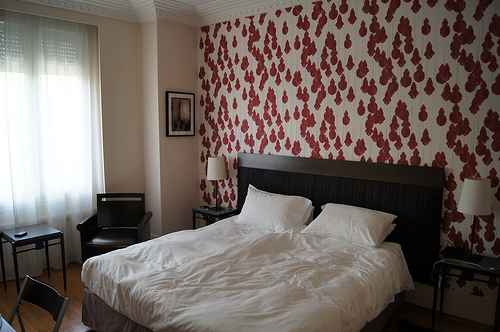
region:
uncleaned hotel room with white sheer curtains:
[2, 2, 498, 329]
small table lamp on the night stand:
[205, 154, 229, 210]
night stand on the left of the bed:
[433, 247, 499, 322]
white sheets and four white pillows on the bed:
[81, 150, 442, 328]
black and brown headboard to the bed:
[234, 151, 445, 281]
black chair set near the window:
[77, 189, 151, 271]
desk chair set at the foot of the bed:
[0, 271, 71, 330]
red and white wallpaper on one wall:
[199, 0, 496, 323]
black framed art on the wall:
[163, 90, 196, 138]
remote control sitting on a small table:
[0, 219, 71, 292]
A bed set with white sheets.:
[57, 136, 452, 321]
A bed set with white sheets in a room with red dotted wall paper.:
[23, 19, 471, 319]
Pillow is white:
[299, 202, 397, 246]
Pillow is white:
[235, 182, 310, 234]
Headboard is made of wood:
[235, 152, 443, 286]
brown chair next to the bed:
[75, 190, 154, 266]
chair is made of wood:
[75, 190, 150, 260]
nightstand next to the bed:
[190, 200, 235, 225]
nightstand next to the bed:
[77, 211, 404, 326]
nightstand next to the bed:
[430, 245, 496, 325]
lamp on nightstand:
[455, 175, 490, 255]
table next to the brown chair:
[0, 221, 67, 296]